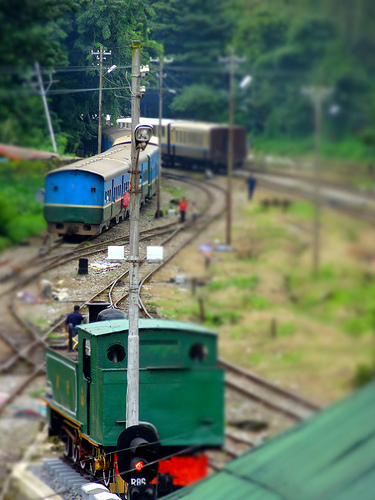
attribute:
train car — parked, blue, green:
[43, 142, 163, 243]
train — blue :
[48, 157, 204, 227]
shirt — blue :
[65, 312, 93, 343]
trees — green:
[234, 395, 260, 434]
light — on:
[134, 461, 144, 472]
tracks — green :
[42, 318, 234, 459]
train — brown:
[92, 110, 254, 179]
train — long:
[43, 125, 130, 234]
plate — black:
[114, 438, 136, 472]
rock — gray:
[97, 269, 108, 280]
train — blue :
[39, 136, 161, 243]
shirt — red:
[179, 203, 187, 212]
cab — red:
[49, 303, 220, 480]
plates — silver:
[39, 460, 84, 495]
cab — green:
[41, 318, 223, 494]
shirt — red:
[178, 204, 188, 214]